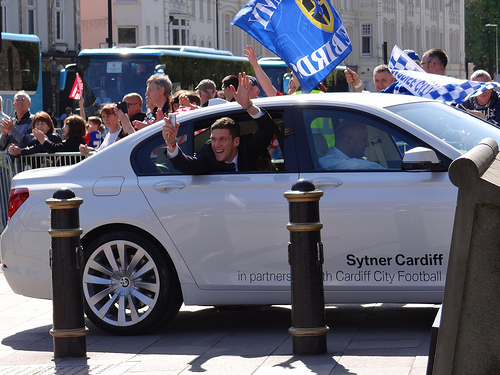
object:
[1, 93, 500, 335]
sedan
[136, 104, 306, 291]
doors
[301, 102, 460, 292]
doors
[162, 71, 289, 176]
man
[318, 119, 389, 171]
man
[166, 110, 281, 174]
jacket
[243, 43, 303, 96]
person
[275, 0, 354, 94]
flag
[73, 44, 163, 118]
bus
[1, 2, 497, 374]
city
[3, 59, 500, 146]
crowd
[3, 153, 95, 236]
fence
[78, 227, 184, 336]
tire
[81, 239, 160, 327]
rims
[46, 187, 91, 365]
pole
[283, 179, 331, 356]
pole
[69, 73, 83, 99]
flag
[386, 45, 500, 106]
banner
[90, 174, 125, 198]
gas tank door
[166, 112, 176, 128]
phone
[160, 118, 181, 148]
hand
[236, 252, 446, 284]
writing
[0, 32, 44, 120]
bus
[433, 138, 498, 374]
gray object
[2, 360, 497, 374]
sidewalk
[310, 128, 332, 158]
front seat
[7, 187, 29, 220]
tail light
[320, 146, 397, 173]
shirt